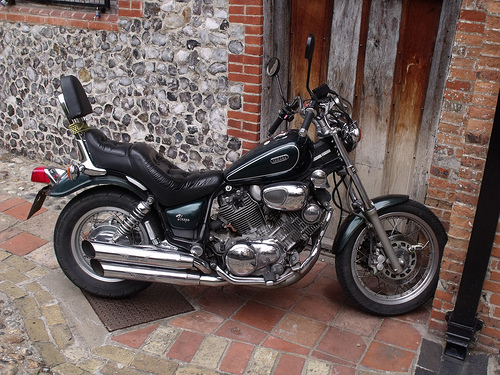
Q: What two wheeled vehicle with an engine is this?
A: Motorcycle.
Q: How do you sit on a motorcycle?
A: Seat.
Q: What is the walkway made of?
A: Bricks.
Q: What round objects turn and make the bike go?
A: Wheels.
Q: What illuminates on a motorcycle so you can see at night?
A: Headlight.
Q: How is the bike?
A: Parked.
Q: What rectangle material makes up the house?
A: Bricks.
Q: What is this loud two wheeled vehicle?
A: Motorcycle.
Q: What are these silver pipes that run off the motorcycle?
A: Exhaust.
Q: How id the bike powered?
A: Engine.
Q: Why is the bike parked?
A: Not in use.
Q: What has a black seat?
A: Motorcycle.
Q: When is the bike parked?
A: During the light of day.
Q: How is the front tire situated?
A: In a corner.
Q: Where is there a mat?
A: Under back tire.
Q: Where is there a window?
A: Top left.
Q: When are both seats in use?
A: If there's a passenger.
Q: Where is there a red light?
A: Back of bike.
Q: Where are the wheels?
A: On bike.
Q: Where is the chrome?
A: On bike.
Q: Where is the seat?
A: On bike.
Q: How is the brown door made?
A: Of wood.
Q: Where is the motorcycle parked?
A: Front of building.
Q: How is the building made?
A: Of bricks.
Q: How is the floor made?
A: Of bricks.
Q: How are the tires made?
A: Rubber.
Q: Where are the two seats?
A: On motorbike.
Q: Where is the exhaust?
A: On motorcycle.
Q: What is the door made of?
A: Wood.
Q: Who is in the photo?
A: Nobody.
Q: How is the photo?
A: Clear.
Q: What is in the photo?
A: A bike.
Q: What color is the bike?
A: Black.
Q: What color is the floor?
A: Brown.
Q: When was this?
A: Daytime.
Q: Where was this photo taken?
A: On a brick sidewalk.